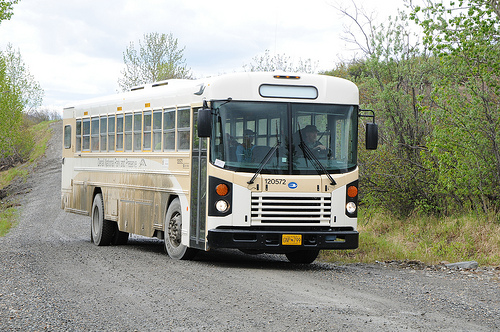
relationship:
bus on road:
[61, 69, 379, 269] [13, 218, 498, 330]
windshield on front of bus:
[209, 98, 357, 173] [61, 69, 379, 269]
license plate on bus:
[273, 222, 317, 256] [36, 52, 401, 294]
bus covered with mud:
[40, 60, 376, 288] [129, 201, 150, 222]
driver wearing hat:
[293, 122, 333, 159] [303, 124, 320, 133]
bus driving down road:
[61, 73, 359, 260] [0, 119, 498, 330]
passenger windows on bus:
[62, 114, 240, 190] [61, 69, 379, 269]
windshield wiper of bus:
[245, 140, 281, 185] [61, 69, 379, 269]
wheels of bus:
[85, 188, 204, 263] [61, 69, 379, 269]